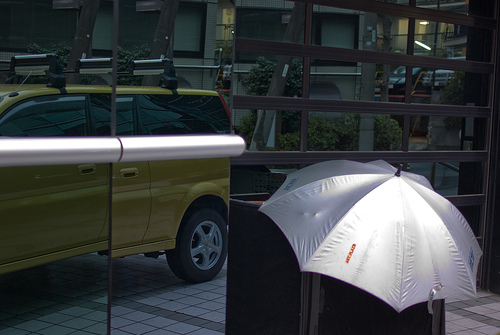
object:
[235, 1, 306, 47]
window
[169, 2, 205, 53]
window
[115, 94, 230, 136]
light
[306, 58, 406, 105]
window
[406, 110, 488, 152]
window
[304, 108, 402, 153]
window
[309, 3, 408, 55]
window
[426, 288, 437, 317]
strap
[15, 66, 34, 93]
antenna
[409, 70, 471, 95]
window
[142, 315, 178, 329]
tiles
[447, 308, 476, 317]
tiles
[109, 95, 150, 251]
door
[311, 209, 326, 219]
bump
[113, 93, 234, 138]
window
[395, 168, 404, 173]
black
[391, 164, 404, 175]
cap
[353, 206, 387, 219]
white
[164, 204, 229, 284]
tire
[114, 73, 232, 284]
vehicle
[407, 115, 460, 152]
rectangular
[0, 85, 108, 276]
reflection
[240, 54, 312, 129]
tree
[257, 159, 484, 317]
umbrella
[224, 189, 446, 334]
bin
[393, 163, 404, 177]
top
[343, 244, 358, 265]
label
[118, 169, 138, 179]
handle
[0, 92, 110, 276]
car door